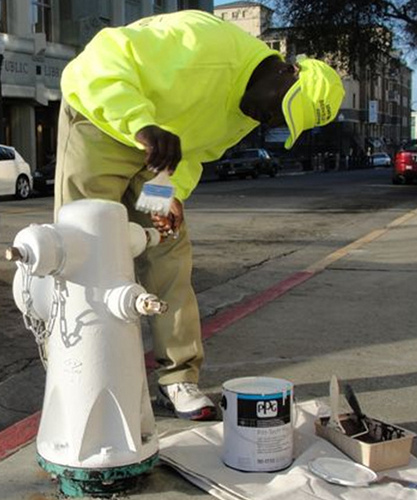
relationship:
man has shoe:
[117, 21, 335, 352] [166, 379, 222, 423]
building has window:
[14, 12, 73, 101] [43, 27, 88, 65]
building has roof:
[14, 12, 73, 101] [227, 2, 254, 12]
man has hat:
[117, 21, 335, 352] [287, 50, 343, 132]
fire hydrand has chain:
[30, 200, 171, 461] [21, 295, 66, 347]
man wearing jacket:
[117, 21, 335, 352] [130, 13, 239, 148]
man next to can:
[117, 21, 335, 352] [231, 359, 298, 470]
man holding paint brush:
[117, 21, 335, 352] [135, 167, 169, 223]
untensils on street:
[321, 381, 376, 440] [0, 167, 417, 499]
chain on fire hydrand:
[21, 295, 66, 347] [30, 200, 171, 461]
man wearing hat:
[117, 21, 335, 352] [287, 50, 343, 132]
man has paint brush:
[117, 21, 335, 352] [135, 167, 169, 223]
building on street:
[14, 12, 73, 101] [217, 200, 290, 254]